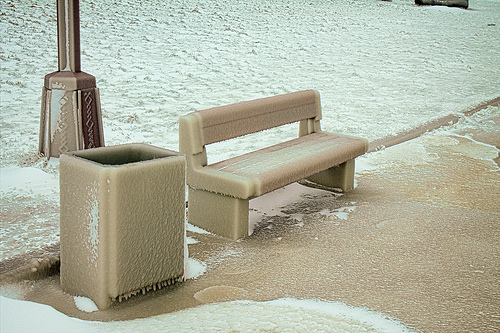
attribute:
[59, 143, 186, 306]
trash can — tan, big, frozen, snow-covered, ice-covered, white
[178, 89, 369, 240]
bench — frozen, ice-covered, plastic, white, brown, icy, tan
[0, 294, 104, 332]
snow — white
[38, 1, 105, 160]
light — metal, snow-covered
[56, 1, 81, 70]
post — brown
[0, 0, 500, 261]
grass — snow-covered, snowy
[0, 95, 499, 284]
curb — icy, cement